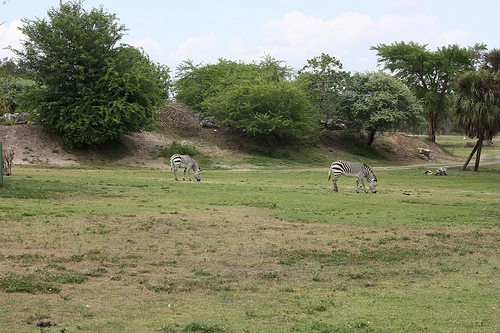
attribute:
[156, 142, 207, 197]
zebra — black, striped, white, grazing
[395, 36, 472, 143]
tree — large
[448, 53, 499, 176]
tree — large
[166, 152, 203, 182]
zebra — grazing, black, white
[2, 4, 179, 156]
bush — large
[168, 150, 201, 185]
zebra — black, white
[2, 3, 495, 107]
sky — clear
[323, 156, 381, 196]
zebra — black, white, grazing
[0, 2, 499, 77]
sky — cloudy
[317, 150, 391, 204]
zebra — black, white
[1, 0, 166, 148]
tree — green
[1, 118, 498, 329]
ground — brown, green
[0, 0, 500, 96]
sky — blue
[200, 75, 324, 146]
bush — green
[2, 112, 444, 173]
hill — brown, small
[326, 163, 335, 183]
tail — long 